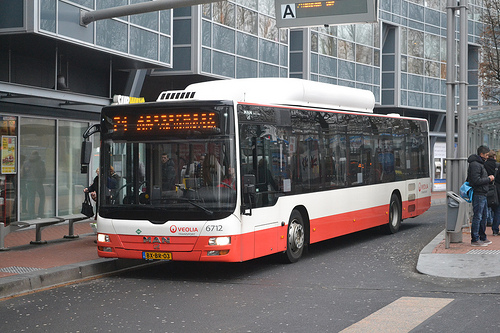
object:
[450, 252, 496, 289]
sidewalk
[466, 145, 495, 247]
man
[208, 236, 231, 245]
headlight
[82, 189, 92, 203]
handles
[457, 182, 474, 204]
bag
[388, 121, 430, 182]
window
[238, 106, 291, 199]
windows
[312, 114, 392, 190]
windows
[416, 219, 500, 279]
sidewalk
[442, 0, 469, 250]
post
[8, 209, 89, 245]
bench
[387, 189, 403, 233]
wheel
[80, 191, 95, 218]
black purse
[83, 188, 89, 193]
persons hand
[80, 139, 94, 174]
side mirror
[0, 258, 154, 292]
curb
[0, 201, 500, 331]
street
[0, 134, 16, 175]
sign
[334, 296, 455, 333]
line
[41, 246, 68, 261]
brick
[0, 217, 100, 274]
sidewalk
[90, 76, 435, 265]
bus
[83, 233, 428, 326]
street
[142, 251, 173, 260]
license plate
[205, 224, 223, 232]
number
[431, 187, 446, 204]
sidewalk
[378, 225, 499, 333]
sidewalk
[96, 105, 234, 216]
windshield